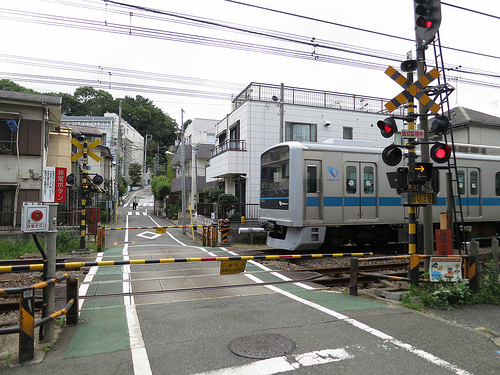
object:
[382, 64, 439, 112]
crossing sign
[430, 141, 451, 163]
flash lights